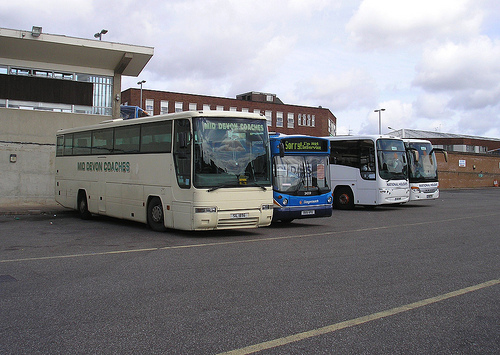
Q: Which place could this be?
A: It is a street.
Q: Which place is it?
A: It is a street.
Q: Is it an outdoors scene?
A: Yes, it is outdoors.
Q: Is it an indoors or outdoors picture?
A: It is outdoors.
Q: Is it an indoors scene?
A: No, it is outdoors.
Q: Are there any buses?
A: Yes, there is a bus.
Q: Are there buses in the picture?
A: Yes, there is a bus.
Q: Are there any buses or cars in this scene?
A: Yes, there is a bus.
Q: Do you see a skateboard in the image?
A: No, there are no skateboards.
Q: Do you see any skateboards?
A: No, there are no skateboards.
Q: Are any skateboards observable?
A: No, there are no skateboards.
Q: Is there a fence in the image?
A: No, there are no fences.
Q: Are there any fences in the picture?
A: No, there are no fences.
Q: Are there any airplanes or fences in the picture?
A: No, there are no fences or airplanes.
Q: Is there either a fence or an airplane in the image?
A: No, there are no fences or airplanes.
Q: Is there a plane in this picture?
A: No, there are no airplanes.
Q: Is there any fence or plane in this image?
A: No, there are no airplanes or fences.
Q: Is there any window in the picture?
A: Yes, there is a window.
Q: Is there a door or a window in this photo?
A: Yes, there is a window.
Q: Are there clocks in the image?
A: No, there are no clocks.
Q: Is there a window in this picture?
A: Yes, there is a window.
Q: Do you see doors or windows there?
A: Yes, there is a window.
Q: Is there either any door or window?
A: Yes, there is a window.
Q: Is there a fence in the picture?
A: No, there are no fences.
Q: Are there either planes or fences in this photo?
A: No, there are no fences or planes.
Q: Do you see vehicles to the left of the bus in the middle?
A: Yes, there is a vehicle to the left of the bus.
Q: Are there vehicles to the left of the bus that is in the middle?
A: Yes, there is a vehicle to the left of the bus.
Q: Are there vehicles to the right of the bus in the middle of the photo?
A: No, the vehicle is to the left of the bus.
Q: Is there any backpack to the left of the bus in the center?
A: No, there is a vehicle to the left of the bus.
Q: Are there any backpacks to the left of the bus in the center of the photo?
A: No, there is a vehicle to the left of the bus.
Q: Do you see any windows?
A: Yes, there is a window.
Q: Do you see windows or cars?
A: Yes, there is a window.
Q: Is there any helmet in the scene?
A: No, there are no helmets.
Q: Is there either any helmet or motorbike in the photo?
A: No, there are no helmets or motorcycles.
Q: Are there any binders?
A: No, there are no binders.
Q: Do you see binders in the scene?
A: No, there are no binders.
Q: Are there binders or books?
A: No, there are no binders or books.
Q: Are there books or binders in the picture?
A: No, there are no binders or books.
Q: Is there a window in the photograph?
A: Yes, there is a window.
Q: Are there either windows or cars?
A: Yes, there is a window.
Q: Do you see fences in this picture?
A: No, there are no fences.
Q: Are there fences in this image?
A: No, there are no fences.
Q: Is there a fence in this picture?
A: No, there are no fences.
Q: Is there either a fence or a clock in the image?
A: No, there are no fences or clocks.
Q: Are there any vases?
A: No, there are no vases.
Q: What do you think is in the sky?
A: The clouds are in the sky.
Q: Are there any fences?
A: No, there are no fences.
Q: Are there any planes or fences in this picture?
A: No, there are no fences or planes.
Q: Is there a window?
A: Yes, there is a window.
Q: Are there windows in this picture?
A: Yes, there is a window.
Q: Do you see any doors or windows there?
A: Yes, there is a window.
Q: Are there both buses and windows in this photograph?
A: Yes, there are both a window and a bus.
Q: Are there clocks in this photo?
A: No, there are no clocks.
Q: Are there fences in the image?
A: No, there are no fences.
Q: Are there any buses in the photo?
A: Yes, there are buses.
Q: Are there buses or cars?
A: Yes, there are buses.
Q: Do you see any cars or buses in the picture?
A: Yes, there are buses.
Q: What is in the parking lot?
A: The buses are in the parking lot.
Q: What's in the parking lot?
A: The buses are in the parking lot.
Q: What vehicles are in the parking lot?
A: The vehicles are buses.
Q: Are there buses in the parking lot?
A: Yes, there are buses in the parking lot.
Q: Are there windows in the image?
A: Yes, there is a window.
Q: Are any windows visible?
A: Yes, there is a window.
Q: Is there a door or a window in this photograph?
A: Yes, there is a window.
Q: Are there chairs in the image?
A: No, there are no chairs.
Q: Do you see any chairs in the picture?
A: No, there are no chairs.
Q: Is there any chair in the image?
A: No, there are no chairs.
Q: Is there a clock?
A: No, there are no clocks.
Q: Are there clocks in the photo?
A: No, there are no clocks.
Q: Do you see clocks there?
A: No, there are no clocks.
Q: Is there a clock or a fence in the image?
A: No, there are no clocks or fences.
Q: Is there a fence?
A: No, there are no fences.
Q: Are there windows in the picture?
A: Yes, there is a window.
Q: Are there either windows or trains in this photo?
A: Yes, there is a window.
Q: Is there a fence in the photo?
A: No, there are no fences.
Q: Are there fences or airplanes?
A: No, there are no fences or airplanes.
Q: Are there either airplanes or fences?
A: No, there are no fences or airplanes.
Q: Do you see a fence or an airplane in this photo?
A: No, there are no fences or airplanes.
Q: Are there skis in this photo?
A: No, there are no skis.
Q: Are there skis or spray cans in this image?
A: No, there are no skis or spray cans.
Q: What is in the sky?
A: The clouds are in the sky.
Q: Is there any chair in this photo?
A: No, there are no chairs.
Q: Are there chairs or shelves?
A: No, there are no chairs or shelves.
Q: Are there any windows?
A: Yes, there is a window.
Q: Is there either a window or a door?
A: Yes, there is a window.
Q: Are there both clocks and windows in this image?
A: No, there is a window but no clocks.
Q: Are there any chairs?
A: No, there are no chairs.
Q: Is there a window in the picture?
A: Yes, there is a window.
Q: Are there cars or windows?
A: Yes, there is a window.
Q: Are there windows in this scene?
A: Yes, there is a window.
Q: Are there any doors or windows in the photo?
A: Yes, there is a window.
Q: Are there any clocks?
A: No, there are no clocks.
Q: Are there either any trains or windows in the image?
A: Yes, there is a window.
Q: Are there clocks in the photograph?
A: No, there are no clocks.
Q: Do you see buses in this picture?
A: Yes, there is a bus.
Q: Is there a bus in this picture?
A: Yes, there is a bus.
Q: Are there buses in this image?
A: Yes, there is a bus.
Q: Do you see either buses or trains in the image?
A: Yes, there is a bus.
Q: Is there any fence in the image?
A: No, there are no fences.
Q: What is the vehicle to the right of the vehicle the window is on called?
A: The vehicle is a bus.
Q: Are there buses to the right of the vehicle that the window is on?
A: Yes, there is a bus to the right of the vehicle.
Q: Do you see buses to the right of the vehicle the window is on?
A: Yes, there is a bus to the right of the vehicle.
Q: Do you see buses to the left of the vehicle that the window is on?
A: No, the bus is to the right of the vehicle.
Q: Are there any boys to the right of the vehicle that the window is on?
A: No, there is a bus to the right of the vehicle.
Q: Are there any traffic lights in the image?
A: No, there are no traffic lights.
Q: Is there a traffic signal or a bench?
A: No, there are no traffic lights or benches.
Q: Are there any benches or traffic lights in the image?
A: No, there are no traffic lights or benches.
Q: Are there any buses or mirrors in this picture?
A: Yes, there is a bus.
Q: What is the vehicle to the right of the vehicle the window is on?
A: The vehicle is a bus.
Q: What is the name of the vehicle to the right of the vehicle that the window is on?
A: The vehicle is a bus.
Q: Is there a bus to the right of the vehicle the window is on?
A: Yes, there is a bus to the right of the vehicle.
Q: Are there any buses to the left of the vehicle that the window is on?
A: No, the bus is to the right of the vehicle.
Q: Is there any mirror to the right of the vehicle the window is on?
A: No, there is a bus to the right of the vehicle.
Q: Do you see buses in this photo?
A: Yes, there is a bus.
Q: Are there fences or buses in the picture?
A: Yes, there is a bus.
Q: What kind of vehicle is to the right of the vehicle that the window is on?
A: The vehicle is a bus.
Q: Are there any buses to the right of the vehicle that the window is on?
A: Yes, there is a bus to the right of the vehicle.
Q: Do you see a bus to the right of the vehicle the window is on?
A: Yes, there is a bus to the right of the vehicle.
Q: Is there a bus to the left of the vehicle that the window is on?
A: No, the bus is to the right of the vehicle.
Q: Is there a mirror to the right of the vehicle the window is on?
A: No, there is a bus to the right of the vehicle.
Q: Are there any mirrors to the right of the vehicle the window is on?
A: No, there is a bus to the right of the vehicle.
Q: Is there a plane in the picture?
A: No, there are no airplanes.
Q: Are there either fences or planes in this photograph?
A: No, there are no planes or fences.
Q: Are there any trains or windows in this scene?
A: Yes, there is a window.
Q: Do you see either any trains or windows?
A: Yes, there is a window.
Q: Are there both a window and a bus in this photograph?
A: Yes, there are both a window and a bus.